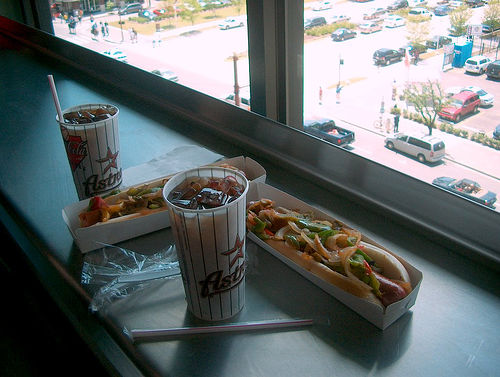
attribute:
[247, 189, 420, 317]
hot dog — chicago style, paper, footlong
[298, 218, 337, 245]
peppers — red, green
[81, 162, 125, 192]
logo — astros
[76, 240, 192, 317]
plastic — empty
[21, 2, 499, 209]
window — glass, large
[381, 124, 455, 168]
van — minivan, white, parked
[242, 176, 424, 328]
holder — white, disposible, cardboard, rectangular, paper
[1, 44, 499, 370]
counter — blue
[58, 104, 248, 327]
cups — paper, soda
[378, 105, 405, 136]
people — walking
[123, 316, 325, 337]
straw — plastic, wraped, wrapped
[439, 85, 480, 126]
suv — red, parked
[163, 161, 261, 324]
cup — paper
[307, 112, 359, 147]
truck — pickup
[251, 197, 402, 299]
bun — bread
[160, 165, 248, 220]
soda — cold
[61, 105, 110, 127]
soda — iced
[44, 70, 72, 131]
straw — white